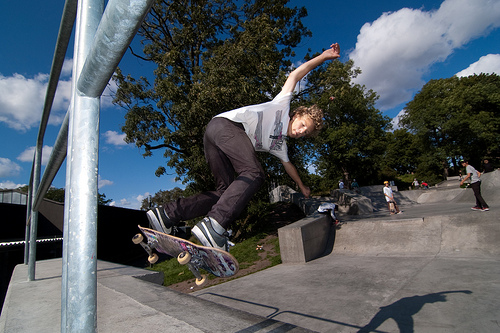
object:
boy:
[145, 41, 339, 252]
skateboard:
[131, 224, 238, 287]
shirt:
[210, 94, 290, 162]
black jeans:
[162, 117, 264, 227]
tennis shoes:
[146, 204, 231, 255]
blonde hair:
[293, 103, 323, 131]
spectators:
[338, 178, 361, 188]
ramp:
[335, 184, 400, 216]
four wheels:
[130, 232, 205, 285]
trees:
[101, 4, 499, 178]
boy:
[383, 180, 401, 213]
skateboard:
[387, 200, 397, 214]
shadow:
[358, 288, 472, 332]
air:
[1, 0, 499, 332]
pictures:
[180, 241, 235, 280]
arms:
[281, 42, 343, 197]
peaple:
[337, 156, 490, 211]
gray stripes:
[255, 110, 286, 150]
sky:
[0, 0, 498, 169]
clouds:
[337, 2, 499, 113]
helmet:
[292, 101, 329, 140]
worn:
[294, 102, 324, 130]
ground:
[0, 185, 496, 332]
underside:
[137, 226, 234, 286]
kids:
[150, 42, 491, 241]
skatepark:
[0, 190, 499, 332]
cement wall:
[268, 185, 332, 265]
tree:
[112, 0, 310, 195]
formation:
[338, 0, 498, 101]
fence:
[25, 0, 154, 332]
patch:
[151, 234, 241, 281]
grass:
[145, 242, 260, 287]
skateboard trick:
[132, 42, 341, 288]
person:
[459, 156, 489, 210]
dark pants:
[469, 181, 486, 208]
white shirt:
[464, 166, 481, 183]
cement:
[0, 171, 499, 333]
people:
[407, 178, 430, 190]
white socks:
[209, 216, 228, 235]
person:
[420, 179, 429, 190]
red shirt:
[422, 182, 427, 186]